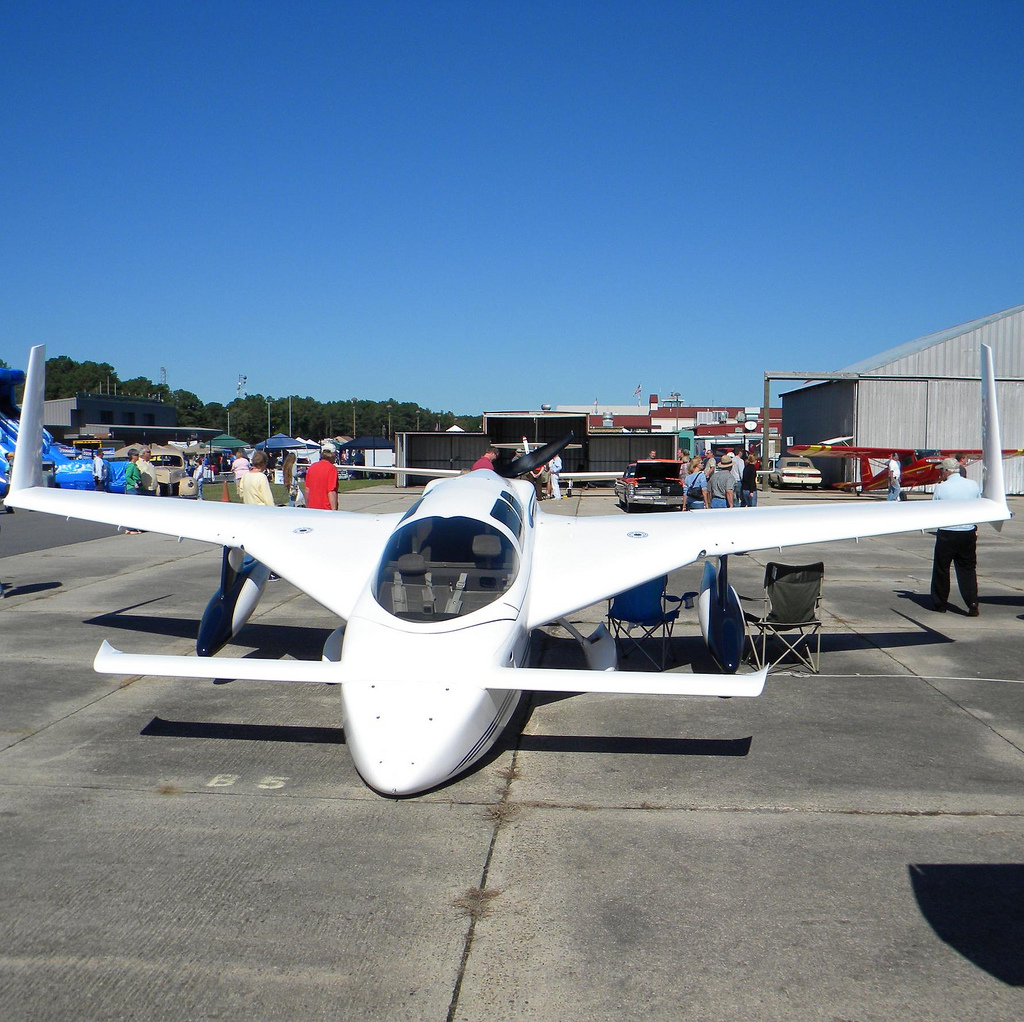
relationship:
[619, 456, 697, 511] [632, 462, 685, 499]
car has bonnet